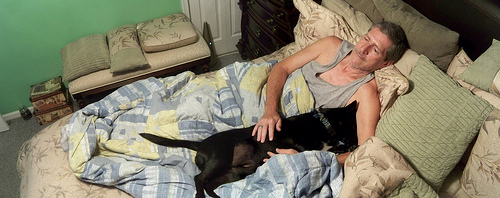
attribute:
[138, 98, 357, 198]
dog — black, sleeping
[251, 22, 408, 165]
man — sleeping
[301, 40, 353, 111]
tank top — grey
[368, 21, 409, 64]
hair — grey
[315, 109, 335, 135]
collar — black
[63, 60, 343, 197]
blanket — crumbled